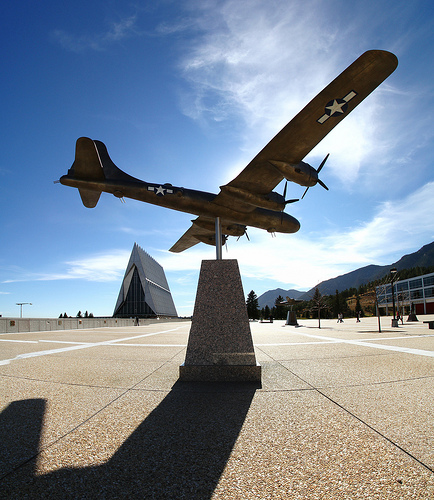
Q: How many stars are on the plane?
A: Two.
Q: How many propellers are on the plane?
A: 4.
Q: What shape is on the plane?
A: Star.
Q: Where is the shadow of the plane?
A: The ground.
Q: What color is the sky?
A: Blue.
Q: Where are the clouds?
A: The sky.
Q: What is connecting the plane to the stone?
A: A pole.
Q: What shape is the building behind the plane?
A: Triangle.